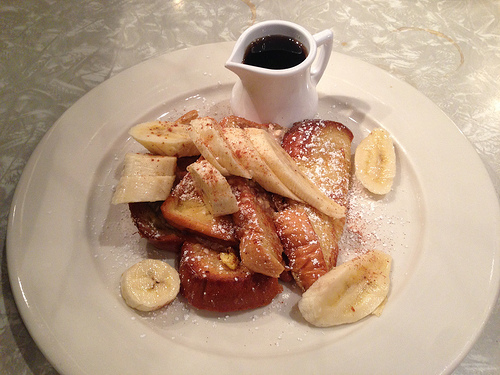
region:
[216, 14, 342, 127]
This is a cup of coffee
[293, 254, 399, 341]
This is a piece of banana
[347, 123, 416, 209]
This is a piece of banana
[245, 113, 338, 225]
This is a piece of banana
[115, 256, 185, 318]
This is a piece of banana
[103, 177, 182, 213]
This is a piece of banana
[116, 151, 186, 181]
This is a piece of banana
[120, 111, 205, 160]
This is a piece of banana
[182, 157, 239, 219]
This is a piece of bananaThis is a piece of banana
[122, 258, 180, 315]
A slice of a banana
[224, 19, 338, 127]
Ceramic pitcher filled with syrup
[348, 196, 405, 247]
Powdered sugar and cinnamon on a plate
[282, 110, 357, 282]
Slice of french toast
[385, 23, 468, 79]
Coffee mug stain on table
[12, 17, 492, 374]
Breakfast dish on a white plate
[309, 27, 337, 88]
White ceramic pitcher handle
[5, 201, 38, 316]
Glares of light on a plate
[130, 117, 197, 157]
Banana slice covered in cinnamon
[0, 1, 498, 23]
Grey patterned table top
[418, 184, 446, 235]
part of a plate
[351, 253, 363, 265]
part of a banana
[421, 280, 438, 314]
part of a plate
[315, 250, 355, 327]
part of a banana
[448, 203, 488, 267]
part of a plate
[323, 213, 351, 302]
part of a banana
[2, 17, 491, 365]
plate is round and white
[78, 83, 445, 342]
plate has round indention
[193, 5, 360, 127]
pitcher of syrup on plate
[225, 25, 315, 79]
syrup is dark brown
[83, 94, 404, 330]
french toast on plate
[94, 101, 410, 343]
bananas on top of toast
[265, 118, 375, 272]
toast sprinkled with powdered sugar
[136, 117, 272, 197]
bananas have cinnamon on top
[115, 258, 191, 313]
banana cut into slice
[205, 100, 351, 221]
banana cut on bias